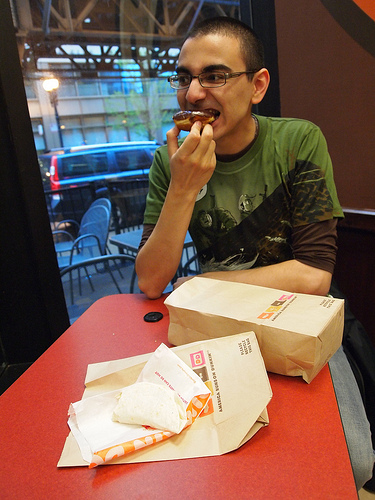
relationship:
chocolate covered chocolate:
[173, 108, 211, 122] [178, 112, 211, 122]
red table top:
[81, 317, 119, 342] [21, 378, 75, 410]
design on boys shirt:
[192, 208, 267, 244] [138, 115, 344, 274]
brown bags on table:
[192, 279, 273, 334] [88, 324, 131, 356]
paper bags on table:
[169, 291, 327, 344] [78, 318, 136, 354]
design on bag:
[251, 295, 301, 322] [192, 279, 273, 334]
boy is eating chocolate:
[135, 23, 375, 487] [173, 108, 211, 122]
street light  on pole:
[40, 77, 72, 144] [48, 102, 80, 140]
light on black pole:
[42, 74, 67, 91] [48, 102, 80, 140]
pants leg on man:
[326, 375, 364, 417] [155, 26, 337, 239]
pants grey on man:
[326, 375, 364, 417] [155, 26, 337, 239]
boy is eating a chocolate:
[155, 26, 337, 239] [173, 108, 211, 122]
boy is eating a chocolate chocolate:
[135, 23, 375, 487] [173, 108, 211, 122]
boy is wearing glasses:
[165, 37, 238, 138] [159, 73, 243, 97]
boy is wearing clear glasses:
[165, 37, 238, 138] [173, 68, 233, 91]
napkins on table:
[105, 358, 190, 415] [78, 318, 136, 354]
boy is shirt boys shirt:
[135, 23, 375, 487] [235, 170, 312, 219]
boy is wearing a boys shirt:
[165, 37, 238, 138] [138, 115, 344, 274]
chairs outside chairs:
[53, 204, 121, 304] [53, 204, 121, 304]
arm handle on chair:
[72, 224, 103, 258] [68, 197, 119, 253]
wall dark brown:
[272, 23, 362, 95] [192, 279, 273, 334]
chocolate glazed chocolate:
[178, 112, 211, 122] [173, 108, 211, 122]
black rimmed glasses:
[198, 74, 238, 86] [159, 73, 243, 97]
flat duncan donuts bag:
[202, 421, 246, 448] [205, 367, 250, 422]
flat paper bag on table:
[202, 421, 246, 448] [78, 318, 136, 354]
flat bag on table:
[202, 421, 246, 448] [88, 324, 131, 356]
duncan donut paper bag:
[187, 348, 233, 430] [205, 367, 250, 422]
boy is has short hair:
[135, 23, 375, 487] [197, 20, 253, 44]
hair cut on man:
[181, 16, 265, 81] [155, 26, 337, 239]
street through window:
[40, 77, 65, 147] [15, 79, 149, 202]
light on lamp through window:
[42, 74, 67, 91] [28, 72, 127, 154]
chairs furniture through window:
[53, 204, 121, 304] [28, 72, 127, 154]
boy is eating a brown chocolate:
[135, 23, 375, 487] [173, 108, 211, 122]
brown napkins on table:
[192, 279, 273, 334] [88, 324, 131, 356]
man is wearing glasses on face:
[159, 73, 243, 97] [165, 37, 238, 138]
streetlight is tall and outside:
[40, 77, 72, 144] [28, 72, 127, 154]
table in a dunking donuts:
[90, 316, 139, 344] [174, 111, 220, 124]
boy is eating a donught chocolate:
[135, 23, 375, 487] [173, 108, 211, 122]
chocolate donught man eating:
[173, 108, 211, 122] [207, 107, 235, 127]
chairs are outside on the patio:
[70, 208, 135, 272] [74, 278, 120, 302]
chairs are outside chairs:
[53, 204, 121, 304] [70, 208, 135, 272]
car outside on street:
[49, 145, 157, 228] [117, 187, 151, 221]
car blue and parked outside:
[60, 151, 146, 186] [38, 115, 155, 197]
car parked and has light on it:
[60, 151, 146, 186] [66, 140, 149, 151]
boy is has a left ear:
[135, 23, 375, 487] [253, 69, 272, 100]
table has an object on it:
[90, 316, 139, 344] [137, 300, 169, 329]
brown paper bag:
[192, 279, 273, 334] [205, 367, 250, 422]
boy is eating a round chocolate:
[135, 23, 375, 487] [173, 108, 211, 122]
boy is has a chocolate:
[135, 23, 375, 487] [173, 108, 211, 122]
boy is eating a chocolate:
[135, 23, 375, 487] [173, 108, 211, 122]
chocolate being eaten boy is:
[173, 108, 211, 122] [135, 23, 375, 487]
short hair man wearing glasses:
[197, 20, 253, 44] [173, 74, 229, 95]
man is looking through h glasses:
[173, 68, 233, 91] [159, 73, 243, 97]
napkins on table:
[111, 341, 212, 435] [90, 316, 139, 344]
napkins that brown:
[111, 341, 212, 435] [105, 358, 190, 415]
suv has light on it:
[60, 151, 146, 186] [137, 300, 169, 329]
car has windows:
[49, 145, 157, 228] [64, 160, 114, 179]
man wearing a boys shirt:
[235, 170, 312, 219] [138, 115, 344, 274]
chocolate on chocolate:
[178, 112, 211, 122] [173, 108, 211, 122]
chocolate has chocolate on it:
[173, 108, 211, 122] [179, 115, 211, 127]